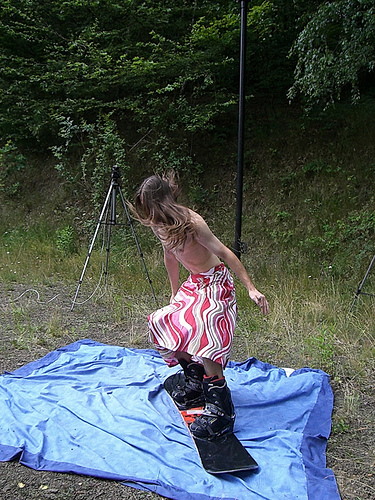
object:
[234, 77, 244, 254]
wood pole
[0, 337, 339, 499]
blanket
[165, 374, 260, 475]
snowboard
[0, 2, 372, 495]
not shown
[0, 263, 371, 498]
ground